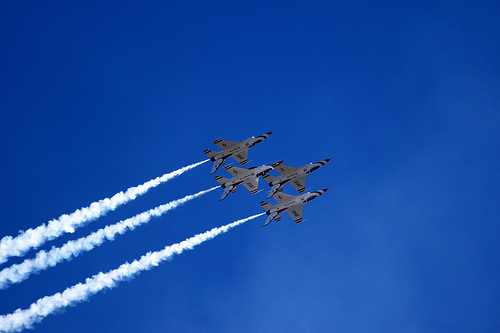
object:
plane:
[202, 130, 276, 176]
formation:
[202, 130, 334, 227]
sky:
[199, 31, 241, 60]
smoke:
[0, 157, 267, 333]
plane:
[214, 160, 285, 201]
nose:
[257, 128, 278, 141]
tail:
[202, 146, 221, 175]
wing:
[212, 135, 241, 150]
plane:
[260, 188, 331, 228]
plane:
[262, 156, 336, 195]